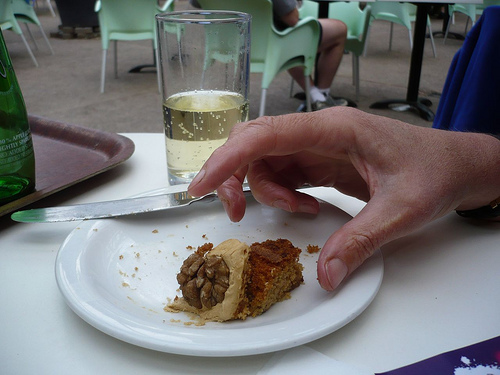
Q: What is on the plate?
A: Food and knife.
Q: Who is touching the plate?
A: The person.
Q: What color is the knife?
A: Silver.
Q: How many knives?
A: One.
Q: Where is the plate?
A: On the table.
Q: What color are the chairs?
A: Green.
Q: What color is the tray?
A: Brown.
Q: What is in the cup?
A: A drink.